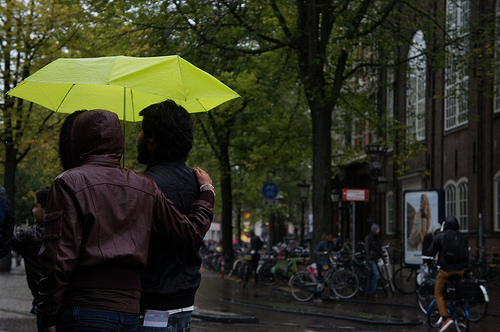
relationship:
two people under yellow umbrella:
[27, 95, 218, 330] [4, 48, 244, 125]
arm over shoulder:
[179, 163, 222, 240] [142, 159, 205, 189]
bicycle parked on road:
[273, 242, 294, 259] [0, 250, 499, 332]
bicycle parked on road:
[286, 248, 360, 302] [0, 250, 499, 332]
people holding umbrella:
[33, 109, 221, 331] [4, 49, 241, 124]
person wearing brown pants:
[419, 216, 472, 332] [428, 262, 470, 322]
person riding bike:
[419, 216, 472, 332] [291, 251, 363, 314]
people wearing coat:
[33, 109, 221, 331] [359, 230, 382, 260]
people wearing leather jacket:
[33, 109, 221, 331] [28, 103, 213, 305]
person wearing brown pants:
[419, 216, 472, 332] [432, 267, 469, 317]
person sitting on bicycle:
[419, 216, 472, 332] [286, 248, 360, 302]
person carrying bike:
[311, 229, 342, 299] [278, 246, 370, 306]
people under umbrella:
[18, 100, 213, 330] [2, 46, 248, 131]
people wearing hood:
[33, 109, 221, 331] [57, 97, 130, 180]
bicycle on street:
[286, 248, 360, 302] [201, 267, 442, 330]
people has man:
[33, 109, 221, 331] [129, 96, 214, 330]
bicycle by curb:
[286, 248, 360, 302] [247, 255, 479, 319]